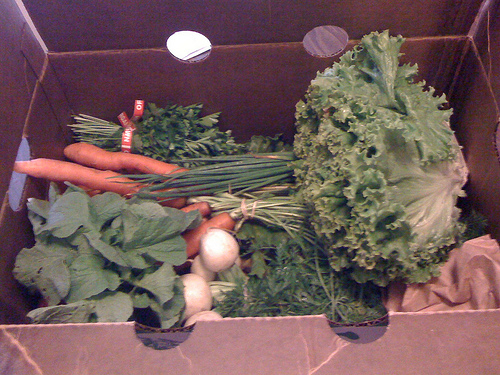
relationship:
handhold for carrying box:
[6, 132, 35, 214] [0, 3, 497, 372]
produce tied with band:
[68, 92, 252, 164] [110, 96, 146, 150]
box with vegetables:
[0, 3, 497, 372] [37, 71, 464, 317]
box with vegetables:
[0, 3, 497, 372] [288, 30, 470, 285]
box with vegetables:
[0, 3, 497, 372] [16, 192, 247, 327]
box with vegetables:
[0, 3, 497, 372] [64, 95, 243, 165]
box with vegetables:
[0, 3, 497, 372] [18, 144, 302, 259]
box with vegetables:
[0, 3, 497, 372] [243, 222, 387, 319]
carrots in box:
[12, 143, 243, 235] [0, 3, 497, 372]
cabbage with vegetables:
[263, 76, 494, 270] [61, 114, 491, 321]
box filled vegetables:
[18, 158, 486, 375] [63, 192, 492, 375]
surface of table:
[37, 19, 417, 48] [18, 7, 497, 372]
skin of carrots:
[20, 137, 200, 215] [11, 140, 185, 197]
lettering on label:
[120, 118, 138, 158] [105, 73, 186, 154]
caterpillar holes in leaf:
[27, 265, 50, 297] [10, 247, 72, 309]